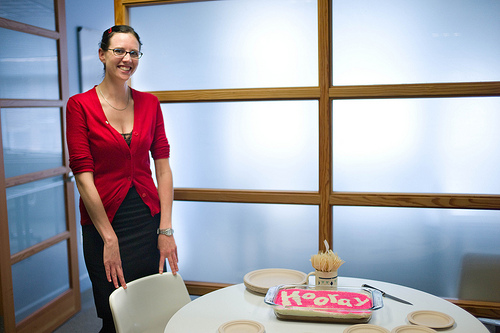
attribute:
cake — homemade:
[274, 286, 375, 323]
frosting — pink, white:
[274, 287, 373, 313]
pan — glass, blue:
[264, 283, 384, 324]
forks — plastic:
[308, 237, 346, 271]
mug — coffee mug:
[305, 269, 340, 288]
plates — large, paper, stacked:
[244, 267, 308, 293]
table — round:
[164, 274, 495, 332]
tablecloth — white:
[160, 276, 493, 332]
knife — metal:
[361, 280, 416, 307]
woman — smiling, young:
[66, 24, 181, 332]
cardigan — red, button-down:
[65, 84, 172, 228]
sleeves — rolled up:
[65, 95, 171, 175]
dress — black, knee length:
[83, 184, 173, 320]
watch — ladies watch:
[155, 226, 177, 236]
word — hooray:
[280, 288, 370, 310]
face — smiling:
[102, 32, 141, 81]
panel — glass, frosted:
[4, 3, 500, 324]